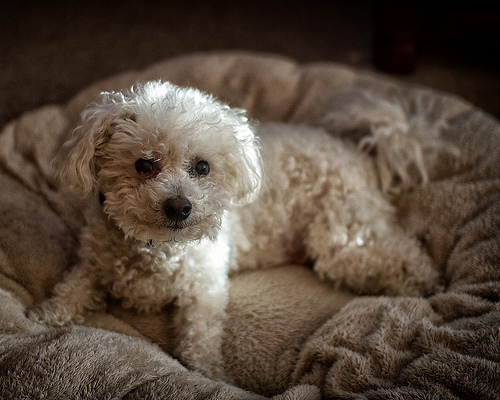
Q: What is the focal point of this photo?
A: A small, fluffy white dog resting.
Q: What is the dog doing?
A: Lying inside a tan pet bed.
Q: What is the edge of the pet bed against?
A: A dark background.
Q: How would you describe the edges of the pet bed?
A: Wrinkles and folds along the edge.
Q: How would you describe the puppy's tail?
A: Flopping in every direction.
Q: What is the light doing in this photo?
A: Falling over puppy's head and leg.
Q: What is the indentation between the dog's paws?
A: A dart seam.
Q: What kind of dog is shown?
A: A poodle.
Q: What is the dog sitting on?
A: A beige pillow.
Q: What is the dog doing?
A: Laying on the pillow.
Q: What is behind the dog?
A: A tail.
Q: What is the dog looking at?
A: The camera.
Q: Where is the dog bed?
A: On the floor.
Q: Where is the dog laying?
A: On dog bed.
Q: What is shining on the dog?
A: The sun.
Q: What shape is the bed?
A: Round.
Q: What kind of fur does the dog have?
A: Curly.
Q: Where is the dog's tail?
A: Laying on the bed.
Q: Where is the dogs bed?
A: On the floor.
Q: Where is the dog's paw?
A: Tucked in the bed.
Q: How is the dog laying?
A: His head up.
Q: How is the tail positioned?
A: It is up.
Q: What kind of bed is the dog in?
A: A fuzzy bed.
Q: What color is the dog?
A: White.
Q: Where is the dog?
A: In a bed.